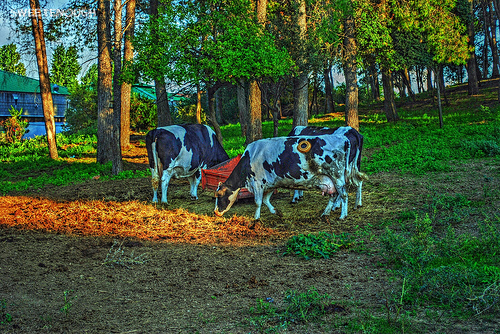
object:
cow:
[211, 133, 350, 219]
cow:
[143, 123, 237, 206]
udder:
[316, 176, 338, 196]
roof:
[0, 69, 70, 94]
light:
[0, 195, 279, 240]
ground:
[0, 77, 500, 333]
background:
[0, 0, 497, 333]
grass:
[0, 111, 499, 333]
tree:
[205, 11, 296, 143]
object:
[295, 141, 312, 155]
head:
[213, 182, 238, 217]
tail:
[341, 137, 350, 184]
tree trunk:
[96, 0, 119, 178]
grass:
[0, 196, 117, 226]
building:
[0, 70, 69, 139]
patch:
[448, 86, 474, 100]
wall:
[13, 122, 68, 142]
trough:
[200, 153, 276, 200]